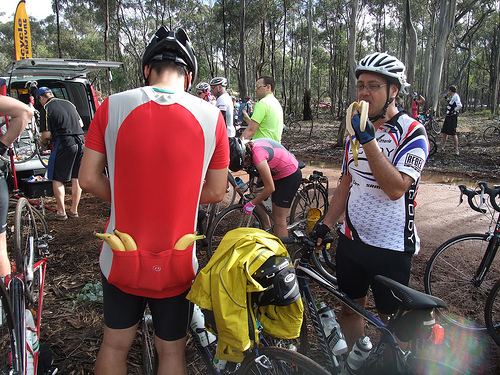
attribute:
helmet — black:
[144, 29, 197, 55]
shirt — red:
[96, 92, 220, 252]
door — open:
[15, 56, 122, 80]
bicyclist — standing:
[4, 28, 474, 337]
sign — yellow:
[14, 0, 32, 60]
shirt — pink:
[252, 142, 297, 180]